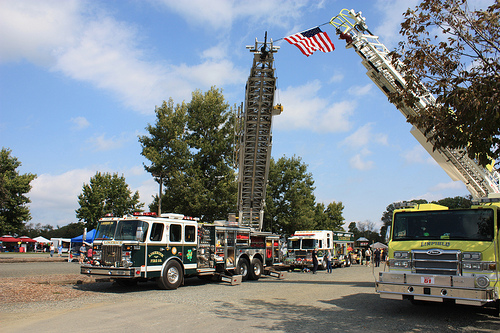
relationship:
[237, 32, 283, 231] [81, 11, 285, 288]
ladder on fire truck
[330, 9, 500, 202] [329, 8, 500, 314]
ladder on fire truck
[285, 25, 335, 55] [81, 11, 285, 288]
flag above fire truck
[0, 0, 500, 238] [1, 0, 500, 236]
clouds in sky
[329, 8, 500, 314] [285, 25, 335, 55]
fire truck under flag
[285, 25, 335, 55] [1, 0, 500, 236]
flag held in sky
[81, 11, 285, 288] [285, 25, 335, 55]
fire truck holding up flag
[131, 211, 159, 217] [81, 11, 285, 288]
lights on fire truck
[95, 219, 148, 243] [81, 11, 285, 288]
windshield on fire truck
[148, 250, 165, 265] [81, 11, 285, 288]
words on fire truck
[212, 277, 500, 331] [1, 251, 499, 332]
shadows on road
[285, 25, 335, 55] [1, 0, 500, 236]
flag in sky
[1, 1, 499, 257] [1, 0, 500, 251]
trees have leaves